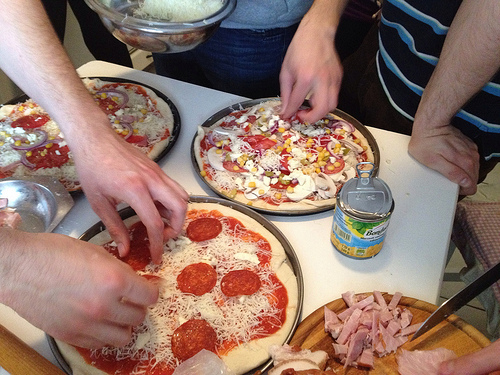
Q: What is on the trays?
A: Pizza.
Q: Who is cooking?
A: People.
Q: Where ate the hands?
A: On the pizzas.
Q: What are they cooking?
A: Pizza.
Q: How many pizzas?
A: 3.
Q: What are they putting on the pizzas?
A: Toppings.